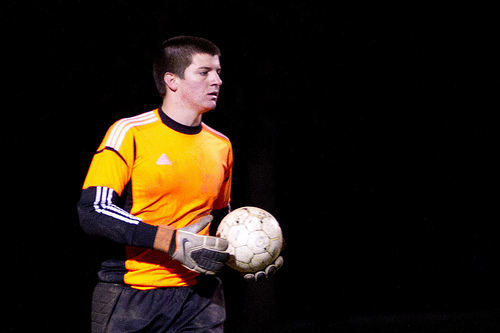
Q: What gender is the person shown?
A: Male.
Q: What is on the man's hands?
A: Gloves.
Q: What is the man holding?
A: Ball.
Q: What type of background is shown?
A: Blackened.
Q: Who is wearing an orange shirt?
A: The man.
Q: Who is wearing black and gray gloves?
A: The man.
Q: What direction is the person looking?
A: Right.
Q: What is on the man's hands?
A: Heavy duty sports gloves.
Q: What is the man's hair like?
A: The hair is closely cropped.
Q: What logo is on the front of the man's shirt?
A: A small triangle.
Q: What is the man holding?
A: A soccer ball.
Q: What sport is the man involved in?
A: A soccer game.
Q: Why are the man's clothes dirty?
A: From playing a soccer game.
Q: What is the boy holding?
A: Soccer ball.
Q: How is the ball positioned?
A: In the boy's hand.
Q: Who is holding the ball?
A: The boy.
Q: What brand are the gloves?
A: Nike.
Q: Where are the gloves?
A: On the boy.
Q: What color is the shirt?
A: Orange.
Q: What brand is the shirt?
A: Adidas.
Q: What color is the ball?
A: White.